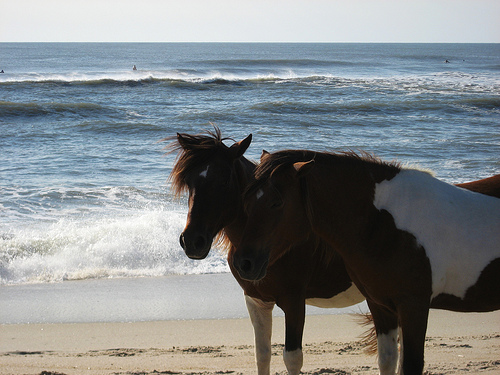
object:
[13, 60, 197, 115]
waves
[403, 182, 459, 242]
whit spot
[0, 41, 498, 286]
ocean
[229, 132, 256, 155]
ear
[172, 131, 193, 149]
ear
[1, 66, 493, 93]
waves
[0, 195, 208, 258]
waves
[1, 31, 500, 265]
waves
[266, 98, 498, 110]
waves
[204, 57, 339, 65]
waves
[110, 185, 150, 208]
ocean waves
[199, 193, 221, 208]
brown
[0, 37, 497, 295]
water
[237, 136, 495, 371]
horse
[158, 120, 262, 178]
mane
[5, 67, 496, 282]
waves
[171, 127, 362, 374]
horse